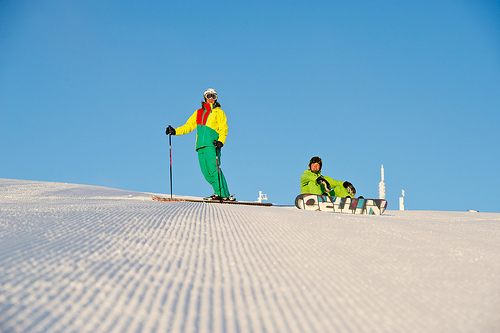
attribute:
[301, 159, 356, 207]
man — One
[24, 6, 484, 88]
sky — clear 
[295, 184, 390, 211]
snowboard — One 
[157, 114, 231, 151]
gloves — black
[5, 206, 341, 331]
snow — freshly manicured 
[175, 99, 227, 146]
jacket — yellow , green 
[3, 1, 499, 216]
sky — blue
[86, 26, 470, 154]
sky — clear blue 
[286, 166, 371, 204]
jacket — green, yellow, neon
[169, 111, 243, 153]
jacket — yellow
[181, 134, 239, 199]
pants — green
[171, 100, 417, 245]
clothes — green, yellow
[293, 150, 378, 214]
man — sitting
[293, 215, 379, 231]
snow — white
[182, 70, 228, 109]
person — standing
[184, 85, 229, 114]
helmet — white, black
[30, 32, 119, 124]
sky — blue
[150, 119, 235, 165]
gloves — black, red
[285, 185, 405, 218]
snowboard — printed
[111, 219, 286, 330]
tracks — ski 